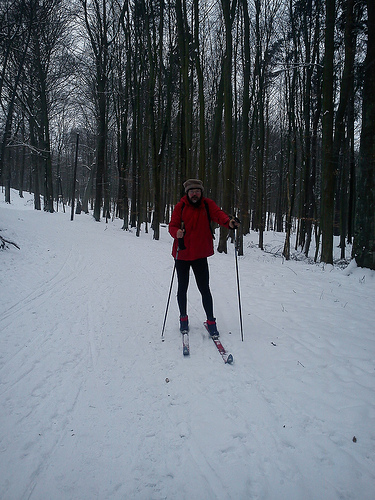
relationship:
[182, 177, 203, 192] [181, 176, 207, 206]
hat on head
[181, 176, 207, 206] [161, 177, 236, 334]
head on man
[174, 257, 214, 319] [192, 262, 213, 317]
tights on leg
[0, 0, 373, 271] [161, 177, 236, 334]
trees behind man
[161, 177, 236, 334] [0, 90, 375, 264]
man in front tree trunks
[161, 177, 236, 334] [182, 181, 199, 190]
man wearing hat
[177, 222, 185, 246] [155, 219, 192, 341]
handle on ski pole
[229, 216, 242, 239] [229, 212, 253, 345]
handle on ski pole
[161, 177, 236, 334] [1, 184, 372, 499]
man on snow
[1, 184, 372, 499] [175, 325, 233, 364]
snow with skis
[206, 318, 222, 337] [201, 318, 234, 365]
foot on ski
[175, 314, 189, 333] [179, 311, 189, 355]
foot on ski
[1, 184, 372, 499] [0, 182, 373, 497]
snow on ground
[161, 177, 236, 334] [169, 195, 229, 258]
man with coat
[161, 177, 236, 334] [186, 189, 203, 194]
man wearing glasses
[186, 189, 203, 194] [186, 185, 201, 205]
glasses on face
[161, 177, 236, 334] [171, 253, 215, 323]
man has pants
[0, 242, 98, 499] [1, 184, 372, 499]
marks on snow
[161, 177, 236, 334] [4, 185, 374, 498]
man in field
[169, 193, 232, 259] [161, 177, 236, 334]
jacket on man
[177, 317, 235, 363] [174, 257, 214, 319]
skis on tights